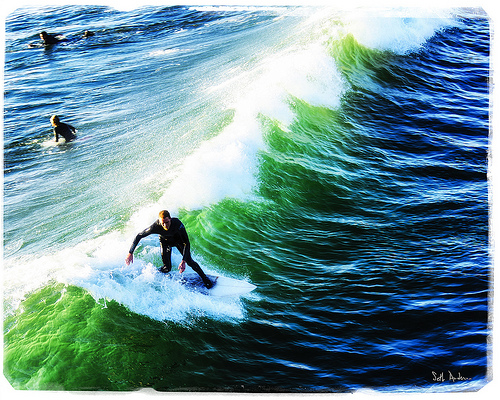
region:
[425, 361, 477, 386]
The signature in the corner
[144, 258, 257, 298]
The man who is standings surfboard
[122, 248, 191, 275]
The man who is standings hands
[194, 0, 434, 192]
The crest of the surf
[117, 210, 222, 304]
A man standing on a surfboard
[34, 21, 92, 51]
A man in a black wet suit swimming away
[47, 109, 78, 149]
A younger man or boy swimming away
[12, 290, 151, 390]
A green part of the ocean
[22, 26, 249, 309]
A group of swimmers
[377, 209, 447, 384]
Dark blue part of the ocean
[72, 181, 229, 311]
the man is surfing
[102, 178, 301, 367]
the man is surfing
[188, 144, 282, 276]
the water is green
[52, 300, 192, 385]
the water is green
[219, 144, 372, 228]
the water is green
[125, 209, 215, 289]
a surfer on a surfboard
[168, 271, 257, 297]
a white surfboard on a wave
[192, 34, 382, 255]
the sun filtering the water to look fluorescent green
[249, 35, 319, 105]
white water splash from the wave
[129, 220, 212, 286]
a black full wetsuit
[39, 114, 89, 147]
a blond surfer sitting on the board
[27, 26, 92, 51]
a surfer laying on his board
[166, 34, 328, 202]
the waves crest is falling apart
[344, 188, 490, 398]
deep blue color ocean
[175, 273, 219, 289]
a blue material on the surfboard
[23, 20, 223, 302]
surfers in the ocean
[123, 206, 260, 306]
surfer riding a wave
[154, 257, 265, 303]
surfboard is white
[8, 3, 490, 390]
ocean is blue and green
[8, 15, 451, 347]
crest of wave is white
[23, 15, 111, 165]
three surfers waiting for a wave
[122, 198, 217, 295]
surfer wearing a wetsuit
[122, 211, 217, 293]
wetsuit is black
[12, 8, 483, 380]
three people surfing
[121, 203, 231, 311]
This is a person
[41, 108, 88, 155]
This is a person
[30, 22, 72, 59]
This is a person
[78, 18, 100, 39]
This is a person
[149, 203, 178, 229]
Head of a person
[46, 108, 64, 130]
Head of a person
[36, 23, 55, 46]
Head of a person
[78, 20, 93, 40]
Head of a person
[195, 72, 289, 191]
This is a lake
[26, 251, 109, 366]
This is a lake